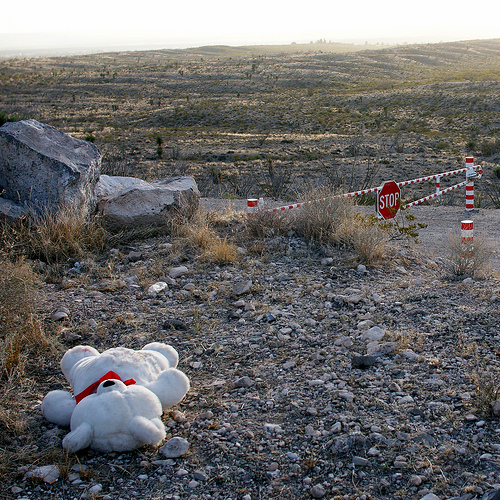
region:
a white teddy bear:
[19, 315, 245, 473]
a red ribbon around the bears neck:
[68, 367, 145, 407]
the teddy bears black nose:
[82, 361, 150, 412]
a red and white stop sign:
[347, 177, 435, 246]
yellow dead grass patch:
[140, 180, 263, 277]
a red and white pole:
[437, 146, 480, 206]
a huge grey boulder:
[2, 88, 127, 263]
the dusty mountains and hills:
[130, 20, 427, 85]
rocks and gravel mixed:
[195, 265, 415, 465]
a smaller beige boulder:
[45, 145, 225, 272]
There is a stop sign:
[380, 183, 412, 223]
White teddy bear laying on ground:
[30, 337, 193, 454]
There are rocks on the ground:
[8, 221, 479, 498]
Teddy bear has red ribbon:
[39, 336, 226, 481]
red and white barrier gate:
[213, 141, 495, 248]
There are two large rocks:
[1, 116, 208, 254]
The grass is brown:
[8, 191, 411, 308]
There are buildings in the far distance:
[307, 36, 404, 55]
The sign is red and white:
[376, 178, 403, 226]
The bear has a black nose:
[36, 332, 217, 470]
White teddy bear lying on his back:
[40, 341, 188, 446]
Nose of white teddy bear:
[92, 375, 124, 395]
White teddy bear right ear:
[120, 415, 160, 450]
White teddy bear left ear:
[55, 420, 95, 446]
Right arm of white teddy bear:
[147, 367, 190, 405]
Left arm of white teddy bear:
[40, 386, 76, 417]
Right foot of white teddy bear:
[136, 336, 178, 364]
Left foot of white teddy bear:
[50, 343, 97, 379]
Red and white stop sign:
[372, 176, 402, 218]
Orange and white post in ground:
[456, 215, 477, 260]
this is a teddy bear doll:
[50, 332, 186, 458]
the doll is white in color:
[47, 330, 189, 455]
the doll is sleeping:
[41, 338, 186, 453]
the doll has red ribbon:
[103, 370, 115, 379]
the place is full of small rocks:
[278, 340, 428, 455]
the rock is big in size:
[11, 126, 71, 192]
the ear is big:
[63, 420, 95, 452]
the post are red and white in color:
[384, 157, 476, 214]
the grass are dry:
[315, 197, 367, 237]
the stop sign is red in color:
[383, 183, 400, 212]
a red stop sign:
[375, 176, 404, 219]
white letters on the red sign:
[378, 191, 399, 209]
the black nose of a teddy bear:
[99, 375, 119, 389]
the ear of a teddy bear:
[126, 406, 171, 454]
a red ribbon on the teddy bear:
[70, 366, 135, 401]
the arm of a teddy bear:
[150, 360, 190, 407]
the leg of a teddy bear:
[140, 335, 183, 367]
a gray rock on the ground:
[305, 402, 320, 416]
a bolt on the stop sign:
[383, 182, 393, 192]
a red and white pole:
[458, 156, 480, 213]